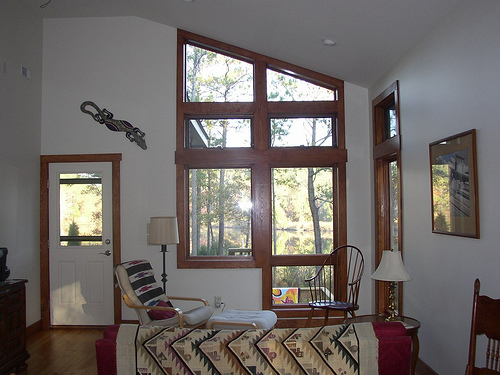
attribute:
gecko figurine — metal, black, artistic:
[79, 98, 148, 151]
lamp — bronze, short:
[370, 249, 409, 320]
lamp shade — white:
[370, 249, 412, 283]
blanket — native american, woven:
[110, 259, 176, 321]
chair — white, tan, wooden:
[114, 255, 213, 328]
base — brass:
[377, 283, 403, 321]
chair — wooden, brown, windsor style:
[304, 243, 366, 327]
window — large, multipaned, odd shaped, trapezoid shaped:
[184, 38, 339, 314]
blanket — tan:
[114, 321, 379, 374]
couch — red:
[94, 321, 412, 373]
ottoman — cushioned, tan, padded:
[207, 305, 277, 331]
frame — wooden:
[173, 25, 347, 321]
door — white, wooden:
[49, 160, 114, 327]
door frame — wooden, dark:
[37, 151, 123, 329]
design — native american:
[133, 324, 359, 374]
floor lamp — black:
[147, 213, 180, 295]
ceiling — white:
[26, 1, 462, 91]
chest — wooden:
[2, 276, 32, 374]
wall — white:
[0, 3, 44, 333]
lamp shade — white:
[145, 213, 180, 246]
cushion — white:
[115, 259, 212, 324]